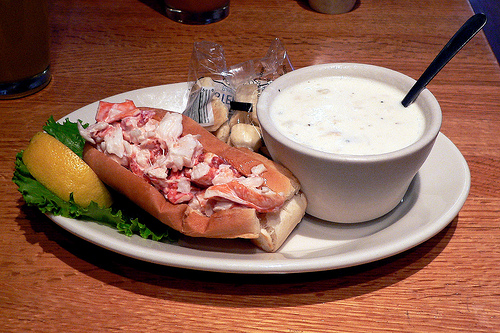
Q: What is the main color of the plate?
A: White.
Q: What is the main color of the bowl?
A: White.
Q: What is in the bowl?
A: Soup.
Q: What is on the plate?
A: Food.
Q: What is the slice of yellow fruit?
A: Lemon.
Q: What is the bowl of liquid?
A: Soup.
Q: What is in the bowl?
A: White sauce.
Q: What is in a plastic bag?
A: Oyster crackers.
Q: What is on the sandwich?
A: Pink meat.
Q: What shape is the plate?
A: Oval.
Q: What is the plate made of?
A: Porcelain.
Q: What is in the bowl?
A: Soup.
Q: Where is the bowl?
A: Next to the bag.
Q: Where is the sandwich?
A: Next to the bowl.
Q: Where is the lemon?
A: Next to the sandwich.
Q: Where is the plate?
A: On the table.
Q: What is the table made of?
A: Wood.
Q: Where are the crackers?
A: In the bag.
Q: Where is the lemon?
A: On lettuce.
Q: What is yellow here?
A: Lemon.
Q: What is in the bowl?
A: Soup.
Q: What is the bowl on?
A: A plate.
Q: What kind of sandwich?
A: Seafood.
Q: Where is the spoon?
A: In the soup.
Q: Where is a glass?
A: Top left.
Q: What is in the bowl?
A: Soup.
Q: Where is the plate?
A: ON a table.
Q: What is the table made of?
A: Wood.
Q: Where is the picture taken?
A: At a table.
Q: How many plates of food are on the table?
A: One.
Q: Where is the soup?
A: In the bowl.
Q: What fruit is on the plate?
A: Lemon.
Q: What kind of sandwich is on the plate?
A: Lobster roll.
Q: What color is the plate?
A: White.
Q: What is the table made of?
A: Wood.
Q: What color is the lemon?
A: Yellow.